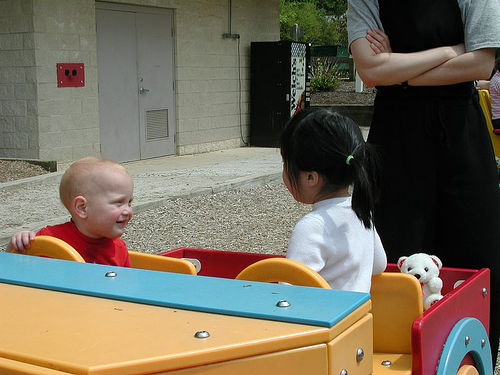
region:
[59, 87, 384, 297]
kids playing outside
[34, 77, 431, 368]
two kids playing outside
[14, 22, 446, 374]
children that are playing outside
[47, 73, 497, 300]
two children playing outside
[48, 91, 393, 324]
children that are sitting outside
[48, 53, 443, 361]
two children that are sitting outside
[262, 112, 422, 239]
a girl with black hair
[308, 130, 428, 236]
a child with black hair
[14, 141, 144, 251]
a younger child sitting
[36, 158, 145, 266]
A baby boy.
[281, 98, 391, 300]
A toddler girl.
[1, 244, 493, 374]
A playground toy truck.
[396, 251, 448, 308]
A stuffed animal.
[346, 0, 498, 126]
A parent stands watching the two kids.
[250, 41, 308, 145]
A vending machine.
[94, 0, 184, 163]
Doors to the mechanics of the building.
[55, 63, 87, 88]
A hazardous sign.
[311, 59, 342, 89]
A bush.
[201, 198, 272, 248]
Gravel and mulch playground.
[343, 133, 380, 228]
hair in pony tails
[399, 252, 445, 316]
teddy bear in wagon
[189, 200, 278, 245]
gravel on the ground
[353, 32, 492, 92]
arms are crossed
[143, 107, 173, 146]
vent in metal door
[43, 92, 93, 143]
building made of cement blocks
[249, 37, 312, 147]
vending machine beside the cement building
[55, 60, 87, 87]
red metal plate on side of building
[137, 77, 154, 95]
chrome handle and lock on door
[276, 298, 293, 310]
metal screws in car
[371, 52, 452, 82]
PERSON ARMS ARE FOLDED TOGRTHER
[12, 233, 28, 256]
BABY HANDS ON THE SEAT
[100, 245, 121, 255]
BOY IS WEARING RED SHIRT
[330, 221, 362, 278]
GIRL HAS ON A WHITE SHIRT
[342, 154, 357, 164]
GIRL HAS A RUBBER BAND AROUND HAIR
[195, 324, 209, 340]
SILVER BOLTS ON TOP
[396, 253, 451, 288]
WHITE TEDDY BEAR IN THE BACK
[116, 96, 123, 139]
GREY DOORS TO THE BUILDING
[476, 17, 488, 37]
PERSON IS WEARING A GREY SHIRT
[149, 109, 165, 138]
VENT MADE INTO THE DOOR